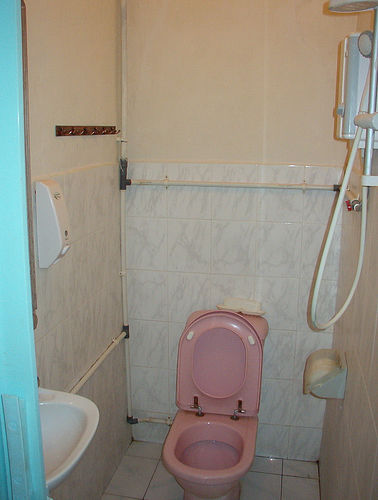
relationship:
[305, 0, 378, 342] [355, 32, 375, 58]
shower has a head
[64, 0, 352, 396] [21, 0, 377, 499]
pipes are outside of wall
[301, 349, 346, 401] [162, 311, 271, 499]
paper holder for toilet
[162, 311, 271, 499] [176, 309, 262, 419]
comode has a seat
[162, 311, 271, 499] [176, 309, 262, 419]
comode has a lid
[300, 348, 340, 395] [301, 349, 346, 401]
toiler paper has a cover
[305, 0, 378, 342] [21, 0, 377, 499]
shower on wall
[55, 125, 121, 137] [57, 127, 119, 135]
hanger has hooks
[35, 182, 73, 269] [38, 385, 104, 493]
soap dispenser above a sink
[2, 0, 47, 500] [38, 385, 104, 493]
door in front of sink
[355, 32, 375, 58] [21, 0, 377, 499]
shower head on wall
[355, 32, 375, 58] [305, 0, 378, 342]
head has a cord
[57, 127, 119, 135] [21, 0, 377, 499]
hooks are on wall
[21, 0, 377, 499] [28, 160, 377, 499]
wall has tiles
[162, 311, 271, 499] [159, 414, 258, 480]
toilet has a bowl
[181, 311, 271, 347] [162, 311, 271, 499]
tank part of comode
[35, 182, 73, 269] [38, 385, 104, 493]
dispenser for washing